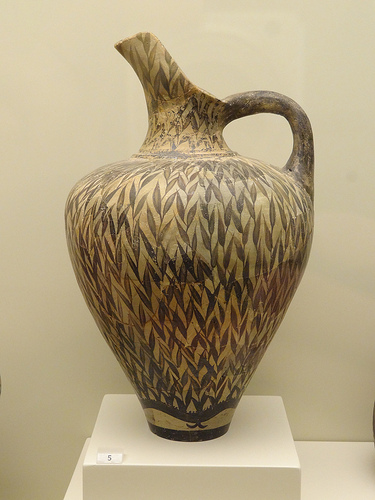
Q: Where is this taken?
A: A museum.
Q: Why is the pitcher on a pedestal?
A: It is on display.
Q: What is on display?
A: A pitcher.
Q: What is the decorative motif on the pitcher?
A: Vines.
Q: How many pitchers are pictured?
A: One.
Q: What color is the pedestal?
A: White.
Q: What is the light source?
A: Interior lighting.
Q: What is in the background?
A: A wall.